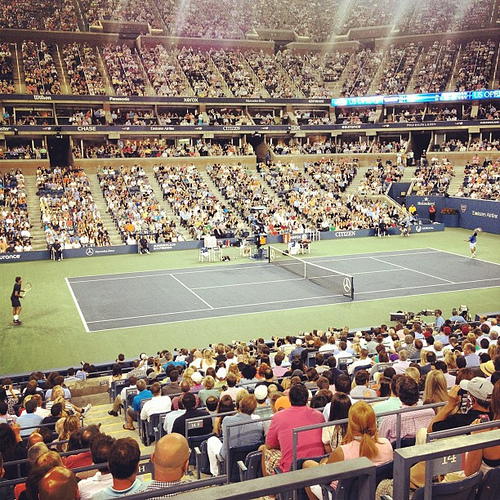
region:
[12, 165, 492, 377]
Photo taken at a tennis match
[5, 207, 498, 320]
Two players on the court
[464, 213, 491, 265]
Player on the right is serving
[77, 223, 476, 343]
The court is blue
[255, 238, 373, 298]
Net in the middle of the court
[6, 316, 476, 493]
Spectators watching the match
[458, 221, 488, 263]
Player wearing a blue shirt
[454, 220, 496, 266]
Player wearing white shorts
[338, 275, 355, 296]
Mercedes symbol on the net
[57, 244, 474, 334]
The lines on the court are white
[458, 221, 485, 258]
tennis player on court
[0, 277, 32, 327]
tennis player on court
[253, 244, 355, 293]
net at center court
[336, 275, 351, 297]
mercedes symbol on net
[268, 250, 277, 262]
mercedes symbol on net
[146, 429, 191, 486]
spectator in the stand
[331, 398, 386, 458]
spectator in the stand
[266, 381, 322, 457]
spectator in the stand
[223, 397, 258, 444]
spectator in the stand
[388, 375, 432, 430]
spectator in the stand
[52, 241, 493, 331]
Tennis court in the stadium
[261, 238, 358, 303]
Net on the tennis court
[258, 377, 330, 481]
Man wearing a pink shirt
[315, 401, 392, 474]
Lady with red hair tied in a pony tail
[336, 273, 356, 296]
Mercedes symbol on the tennis net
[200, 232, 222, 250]
Plastic water jug on a table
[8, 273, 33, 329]
Tennis player wearing black shirt and shorts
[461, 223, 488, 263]
Tennis player wearing white shorts and a blue shirt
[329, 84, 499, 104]
Digital marquee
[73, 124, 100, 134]
Chase Bank sign in the bleachers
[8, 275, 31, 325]
a male tennis player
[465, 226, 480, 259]
a tennis player serving ball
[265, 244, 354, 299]
black and white tennis court net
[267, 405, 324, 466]
a man's pink shirt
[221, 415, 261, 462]
a man's blue shirt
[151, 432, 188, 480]
a man's bald head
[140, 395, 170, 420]
a man's white shirt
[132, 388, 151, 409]
a man's blue shirt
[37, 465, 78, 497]
a man's bald head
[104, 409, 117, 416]
a man's black shoe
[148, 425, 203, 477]
the guy is bald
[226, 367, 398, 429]
a lot of people came to watch the event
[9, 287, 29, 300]
the shirt is black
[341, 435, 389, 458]
the shirt is pink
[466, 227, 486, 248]
the shirt is blue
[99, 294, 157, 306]
the court is gray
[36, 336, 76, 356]
the Astor turf is green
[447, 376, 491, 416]
this guy is using binoculars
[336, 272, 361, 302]
the emblem is white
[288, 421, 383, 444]
the railing is gray